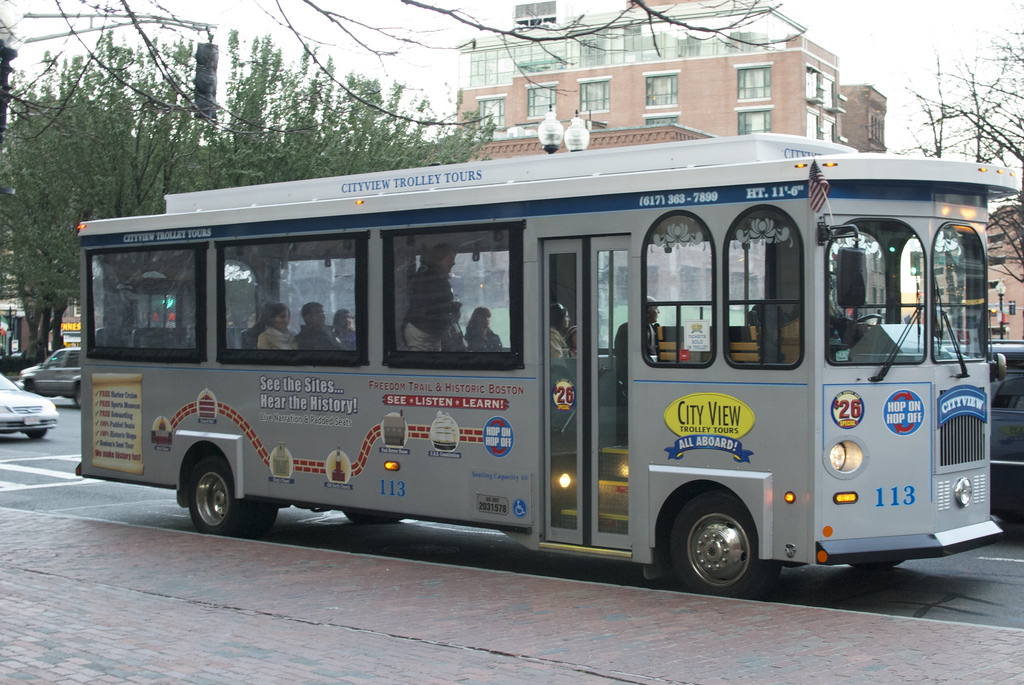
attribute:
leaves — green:
[39, 50, 60, 69]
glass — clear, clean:
[392, 234, 526, 358]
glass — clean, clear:
[737, 206, 815, 371]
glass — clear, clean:
[639, 211, 726, 363]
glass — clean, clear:
[383, 224, 546, 373]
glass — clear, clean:
[204, 221, 370, 349]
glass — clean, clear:
[81, 243, 199, 362]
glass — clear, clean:
[833, 220, 926, 372]